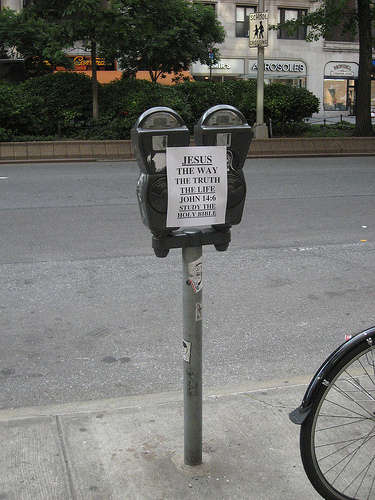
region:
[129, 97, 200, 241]
The parking meter on the left.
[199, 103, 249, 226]
The parking meter on the right.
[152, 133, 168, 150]
The coin slot on the left meter.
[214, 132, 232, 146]
The coin slot on the right meter.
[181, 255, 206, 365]
The stickers on the pole the meters are mounted on.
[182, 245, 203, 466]
The pole the meter is mounted on.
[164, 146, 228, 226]
The white sign taped to the meters.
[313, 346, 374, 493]
The spokes of the bicycle wheel.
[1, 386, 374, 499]
The sidewalk the pole and bicycle are on.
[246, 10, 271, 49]
The school crossing sign across the street.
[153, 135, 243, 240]
a printed white flyer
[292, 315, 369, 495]
part of a bike tire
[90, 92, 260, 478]
a parking meter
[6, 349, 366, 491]
a clean sidewalk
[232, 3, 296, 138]
a school crossing sign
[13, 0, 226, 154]
a large, full tree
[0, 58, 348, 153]
several large green bushes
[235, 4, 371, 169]
a couple store fronts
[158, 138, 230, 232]
a christian flyer that was printed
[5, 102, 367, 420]
an empty street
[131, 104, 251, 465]
a pair of black parking meters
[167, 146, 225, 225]
a sign about Jesus taped to a parking meter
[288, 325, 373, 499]
part of a bicycle tire and black metal fender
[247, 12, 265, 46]
a white school crossing sign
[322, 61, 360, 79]
a white motel sign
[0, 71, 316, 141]
a cluster of green bushes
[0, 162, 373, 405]
a paved street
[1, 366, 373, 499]
a section of concrete sidewalk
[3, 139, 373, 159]
a concrete barrier on the side of a street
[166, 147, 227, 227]
a sign telling people to study the Bible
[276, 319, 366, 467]
Back tire of a bicycle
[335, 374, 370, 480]
Spokes of a bicycle tire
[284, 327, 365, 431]
Mud guard on the back of bicycle tire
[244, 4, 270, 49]
A school crossing sign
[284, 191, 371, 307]
A patch of empty road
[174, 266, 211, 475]
The pole of a parking meter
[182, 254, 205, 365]
Stickers on the pole of a parking meter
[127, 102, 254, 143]
The top of a dual parking meter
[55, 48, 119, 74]
Business name visible through trees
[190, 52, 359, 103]
A row of shops on a city street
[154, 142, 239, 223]
white sign with writing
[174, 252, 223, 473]
grey metal pole on sidewalke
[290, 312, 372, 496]
part of a black bike wheel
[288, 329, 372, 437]
mud guard of bike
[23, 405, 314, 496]
grey paved cement sidewalk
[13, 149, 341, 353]
paved grey empty road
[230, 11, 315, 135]
white sign on metal pole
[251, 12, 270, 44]
white sign with drwaing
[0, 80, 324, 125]
group of green bushes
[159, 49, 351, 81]
building behind green bushes